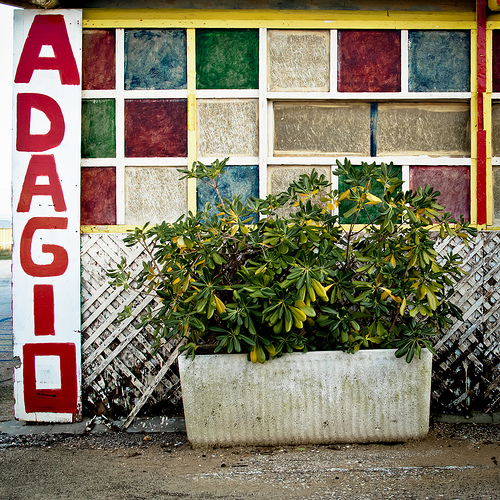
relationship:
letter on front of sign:
[12, 13, 82, 87] [11, 8, 86, 423]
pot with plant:
[176, 346, 434, 449] [106, 156, 479, 365]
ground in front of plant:
[2, 422, 499, 499] [106, 156, 479, 365]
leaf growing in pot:
[285, 268, 304, 281] [176, 346, 434, 449]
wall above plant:
[80, 0, 499, 232] [106, 156, 479, 365]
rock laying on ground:
[173, 440, 185, 449] [2, 422, 499, 499]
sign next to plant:
[11, 8, 86, 423] [106, 156, 479, 365]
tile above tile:
[195, 27, 261, 91] [195, 97, 259, 159]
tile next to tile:
[195, 97, 259, 159] [123, 98, 189, 159]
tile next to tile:
[123, 98, 189, 159] [123, 27, 188, 91]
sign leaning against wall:
[11, 8, 86, 423] [80, 0, 499, 232]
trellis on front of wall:
[82, 230, 499, 416] [80, 0, 499, 232]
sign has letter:
[11, 8, 86, 423] [12, 13, 82, 87]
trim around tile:
[81, 9, 478, 234] [195, 27, 261, 91]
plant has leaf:
[106, 156, 479, 365] [285, 268, 304, 281]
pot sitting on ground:
[176, 346, 434, 449] [2, 422, 499, 499]